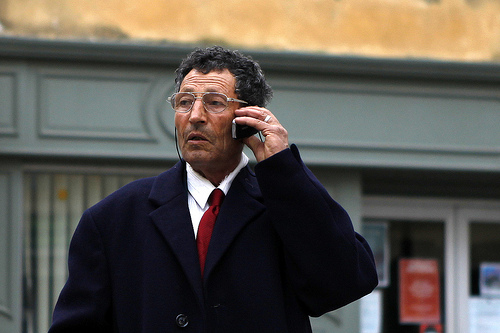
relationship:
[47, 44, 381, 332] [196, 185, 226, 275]
he with tie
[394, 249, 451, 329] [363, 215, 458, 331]
sign on door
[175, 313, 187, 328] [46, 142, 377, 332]
button for coat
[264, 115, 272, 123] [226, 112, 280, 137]
ring on finger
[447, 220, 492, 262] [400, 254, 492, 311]
glassdoor with signs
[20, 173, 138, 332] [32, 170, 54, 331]
valence in window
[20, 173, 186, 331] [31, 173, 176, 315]
valence in window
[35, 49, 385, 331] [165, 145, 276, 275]
he has shirt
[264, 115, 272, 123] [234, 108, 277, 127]
ring on finger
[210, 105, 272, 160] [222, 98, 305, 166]
cellphone in hand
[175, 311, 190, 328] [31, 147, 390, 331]
plastic button on coat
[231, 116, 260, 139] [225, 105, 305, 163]
cellphone in hand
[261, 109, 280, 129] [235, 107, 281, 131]
ring on finger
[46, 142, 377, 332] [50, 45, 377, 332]
coat on main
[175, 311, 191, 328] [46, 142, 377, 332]
plastic button on coat